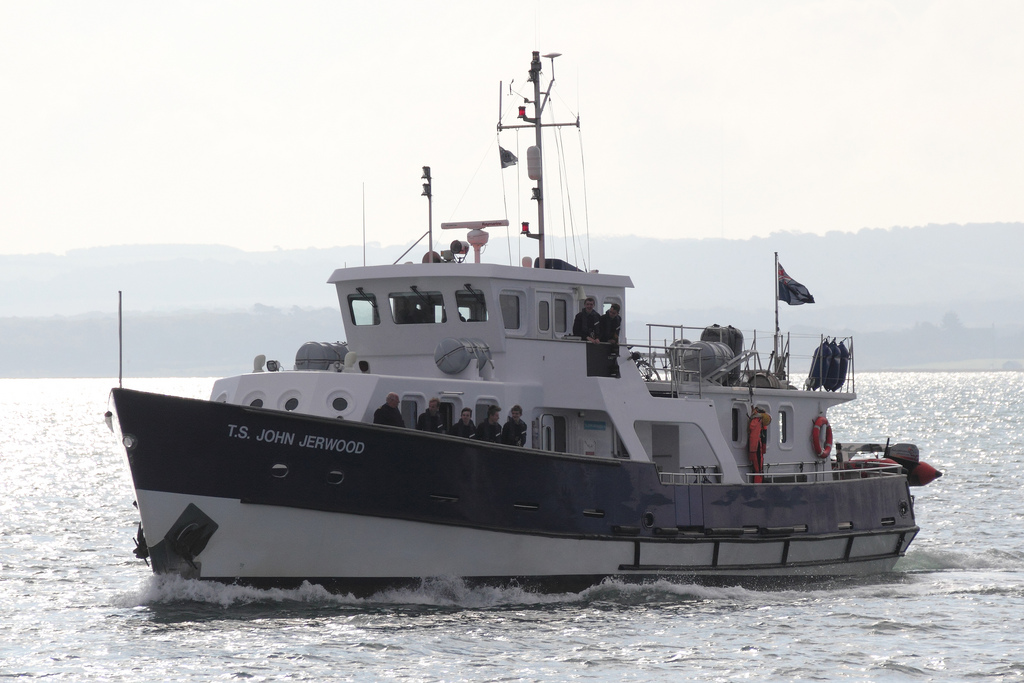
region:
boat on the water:
[62, 45, 989, 606]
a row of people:
[380, 370, 548, 456]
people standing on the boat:
[362, 379, 555, 453]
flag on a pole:
[763, 241, 820, 355]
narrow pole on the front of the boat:
[105, 288, 143, 390]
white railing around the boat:
[661, 466, 895, 485]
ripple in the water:
[870, 611, 957, 640]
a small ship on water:
[106, 55, 942, 583]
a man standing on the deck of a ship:
[371, 394, 406, 424]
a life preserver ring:
[814, 413, 831, 456]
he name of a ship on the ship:
[230, 413, 364, 456]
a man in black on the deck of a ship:
[593, 292, 626, 372]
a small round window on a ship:
[330, 391, 353, 412]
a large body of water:
[6, 371, 1016, 678]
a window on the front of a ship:
[388, 289, 443, 321]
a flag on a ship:
[779, 265, 815, 307]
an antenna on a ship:
[360, 181, 368, 267]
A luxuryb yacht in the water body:
[111, 49, 941, 590]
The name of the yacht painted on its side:
[224, 422, 364, 457]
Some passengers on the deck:
[370, 393, 532, 447]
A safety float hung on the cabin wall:
[810, 415, 831, 464]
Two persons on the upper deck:
[569, 298, 618, 341]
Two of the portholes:
[266, 454, 340, 484]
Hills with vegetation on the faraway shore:
[3, 223, 1018, 373]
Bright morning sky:
[3, 1, 1019, 249]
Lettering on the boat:
[223, 418, 366, 456]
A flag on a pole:
[770, 254, 812, 373]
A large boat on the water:
[103, 46, 939, 579]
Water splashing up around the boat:
[127, 567, 725, 616]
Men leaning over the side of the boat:
[373, 383, 530, 447]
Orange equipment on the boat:
[740, 406, 940, 493]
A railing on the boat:
[620, 526, 911, 566]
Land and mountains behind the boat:
[0, 225, 1019, 374]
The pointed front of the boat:
[103, 377, 199, 581]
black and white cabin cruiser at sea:
[99, 42, 951, 603]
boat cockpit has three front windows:
[325, 260, 633, 377]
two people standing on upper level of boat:
[317, 256, 631, 375]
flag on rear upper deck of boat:
[630, 242, 918, 576]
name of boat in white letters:
[112, 381, 385, 591]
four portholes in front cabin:
[103, 367, 540, 590]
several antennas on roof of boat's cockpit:
[327, 46, 629, 386]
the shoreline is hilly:
[1, 214, 1020, 679]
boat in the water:
[28, 200, 953, 649]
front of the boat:
[6, 239, 475, 603]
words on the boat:
[177, 399, 399, 492]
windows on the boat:
[470, 218, 657, 390]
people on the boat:
[512, 256, 700, 400]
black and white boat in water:
[38, 67, 952, 579]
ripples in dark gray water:
[81, 601, 130, 630]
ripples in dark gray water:
[416, 601, 533, 675]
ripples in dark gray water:
[669, 626, 717, 662]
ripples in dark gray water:
[775, 616, 807, 648]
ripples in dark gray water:
[925, 364, 983, 428]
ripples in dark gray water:
[10, 424, 71, 482]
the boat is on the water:
[2, 48, 1021, 678]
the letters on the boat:
[103, 47, 947, 582]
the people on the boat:
[109, 53, 942, 594]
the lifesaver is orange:
[811, 413, 834, 458]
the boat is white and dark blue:
[106, 47, 941, 613]